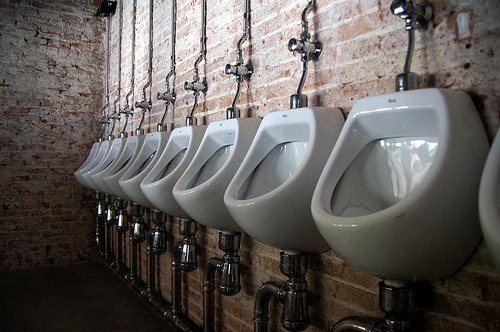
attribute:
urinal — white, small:
[219, 103, 348, 252]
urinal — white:
[305, 85, 499, 282]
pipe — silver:
[242, 251, 313, 331]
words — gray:
[279, 113, 290, 119]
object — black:
[95, 3, 119, 14]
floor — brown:
[0, 257, 184, 329]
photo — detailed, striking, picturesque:
[2, 2, 499, 329]